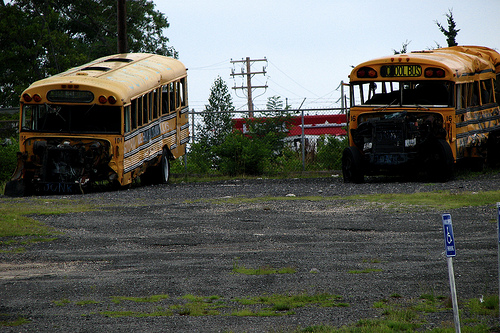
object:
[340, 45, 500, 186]
bus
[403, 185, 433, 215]
grass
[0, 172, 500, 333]
road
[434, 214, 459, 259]
sign